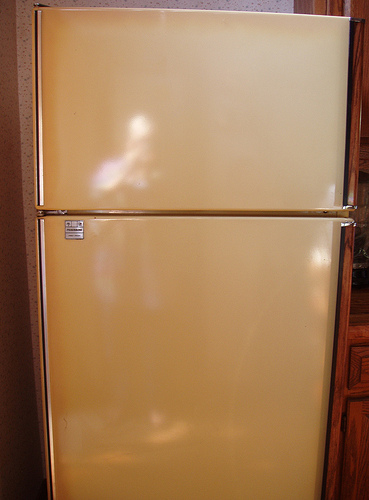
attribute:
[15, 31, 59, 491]
stripe — black and silver, along edge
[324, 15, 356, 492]
handles — wooden, along edge of door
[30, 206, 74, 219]
hinge — silver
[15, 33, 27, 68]
dots — gold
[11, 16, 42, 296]
wall covering — white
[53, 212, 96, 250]
plate — square metal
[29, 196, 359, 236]
space — narrow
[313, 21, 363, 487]
cabinets — wood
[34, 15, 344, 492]
refrigerator — tan, two-door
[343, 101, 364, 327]
storage space — open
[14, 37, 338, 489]
fridge — yellow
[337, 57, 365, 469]
cabinets — made of wood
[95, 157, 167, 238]
man's shirt — blue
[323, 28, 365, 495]
cabinets — brown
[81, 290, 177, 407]
pants — dark colored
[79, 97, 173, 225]
person — white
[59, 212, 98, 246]
magnet — silver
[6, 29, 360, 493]
refrigerator — gold color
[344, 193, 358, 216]
hinges — wood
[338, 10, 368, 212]
trim — wood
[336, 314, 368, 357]
counter — wood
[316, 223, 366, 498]
handle — wood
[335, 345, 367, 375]
drawer — wooden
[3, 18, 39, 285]
wallpaper — speckled, colored